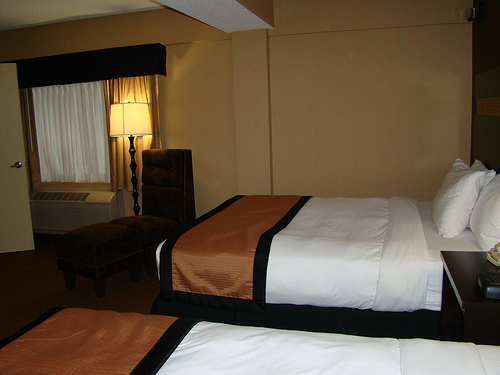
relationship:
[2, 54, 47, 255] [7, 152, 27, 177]
open door with handle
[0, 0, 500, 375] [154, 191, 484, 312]
bedroom with bed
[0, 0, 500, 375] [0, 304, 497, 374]
bedroom with bed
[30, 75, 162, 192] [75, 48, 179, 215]
closed curtains for window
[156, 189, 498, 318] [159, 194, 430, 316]
bed with bed cover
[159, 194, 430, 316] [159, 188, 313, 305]
bed cover with stripe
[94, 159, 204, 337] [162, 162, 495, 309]
chair in front of a bed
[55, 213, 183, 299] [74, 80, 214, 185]
chair next to lamp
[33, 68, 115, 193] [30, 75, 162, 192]
window with closed curtains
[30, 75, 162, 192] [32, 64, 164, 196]
closed curtains on a window